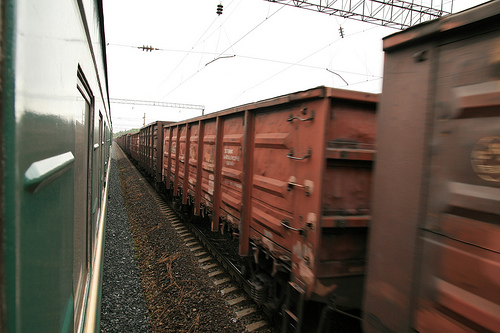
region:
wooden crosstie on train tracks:
[223, 292, 245, 308]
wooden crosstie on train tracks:
[217, 282, 237, 297]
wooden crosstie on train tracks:
[210, 273, 231, 289]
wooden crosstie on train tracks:
[202, 265, 222, 280]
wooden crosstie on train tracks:
[193, 252, 210, 267]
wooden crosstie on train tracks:
[191, 247, 206, 259]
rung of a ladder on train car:
[281, 109, 317, 126]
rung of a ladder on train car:
[281, 145, 315, 164]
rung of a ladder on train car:
[281, 177, 310, 198]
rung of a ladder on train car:
[276, 214, 306, 239]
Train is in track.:
[131, 102, 412, 329]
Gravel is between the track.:
[107, 238, 198, 325]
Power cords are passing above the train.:
[116, 7, 303, 85]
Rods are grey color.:
[326, 4, 438, 29]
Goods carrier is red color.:
[123, 117, 464, 275]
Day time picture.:
[16, 15, 489, 313]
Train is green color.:
[3, 12, 116, 327]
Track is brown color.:
[213, 245, 252, 293]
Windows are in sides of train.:
[58, 63, 111, 330]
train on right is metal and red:
[116, 6, 499, 331]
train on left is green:
[0, 1, 112, 331]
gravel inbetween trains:
[98, 136, 274, 331]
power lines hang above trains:
[102, 3, 459, 129]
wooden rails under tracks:
[117, 143, 271, 331]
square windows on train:
[68, 60, 112, 330]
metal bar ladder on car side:
[280, 90, 321, 329]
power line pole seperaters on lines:
[133, 4, 347, 54]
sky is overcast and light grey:
[103, 0, 495, 130]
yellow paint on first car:
[469, 128, 499, 183]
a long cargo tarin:
[115, 67, 379, 289]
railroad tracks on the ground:
[130, 160, 242, 322]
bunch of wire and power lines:
[127, 13, 280, 107]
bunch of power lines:
[141, 4, 268, 100]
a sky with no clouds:
[125, 0, 169, 27]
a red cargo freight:
[157, 88, 369, 314]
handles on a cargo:
[277, 90, 319, 277]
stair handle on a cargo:
[267, 66, 322, 280]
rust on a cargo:
[322, 123, 374, 150]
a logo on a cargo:
[449, 111, 498, 186]